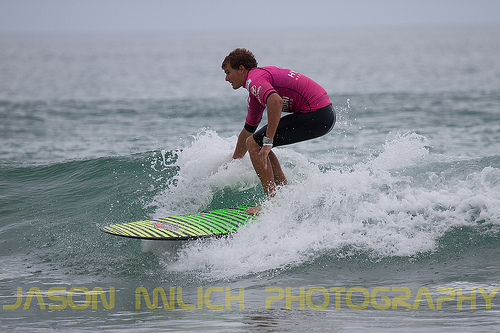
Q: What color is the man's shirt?
A: Pink.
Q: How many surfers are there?
A: One.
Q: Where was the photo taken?
A: The beach.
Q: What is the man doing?
A: Surfing.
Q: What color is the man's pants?
A: Black.